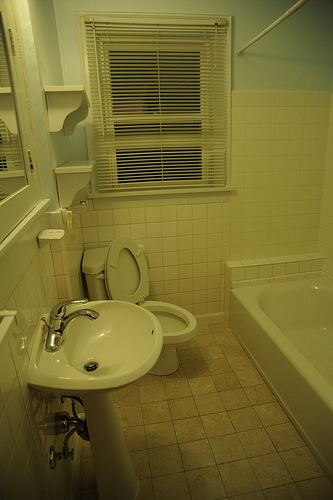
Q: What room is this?
A: Bathroom.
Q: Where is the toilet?
A: Corner of the room.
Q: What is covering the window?
A: Blinds.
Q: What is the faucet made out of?
A: Chrome.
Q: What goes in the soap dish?
A: Soap.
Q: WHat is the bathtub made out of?
A: Porcelain.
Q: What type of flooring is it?
A: Tile.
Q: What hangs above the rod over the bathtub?
A: Shower curtain.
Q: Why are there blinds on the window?
A: To block the view.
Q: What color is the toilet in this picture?
A: White.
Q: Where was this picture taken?
A: A bathroom.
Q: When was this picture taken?
A: Night time.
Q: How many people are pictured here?
A: Zero.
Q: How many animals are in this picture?
A: Zero.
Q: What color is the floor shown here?
A: Tan.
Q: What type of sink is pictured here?
A: Pedestal.